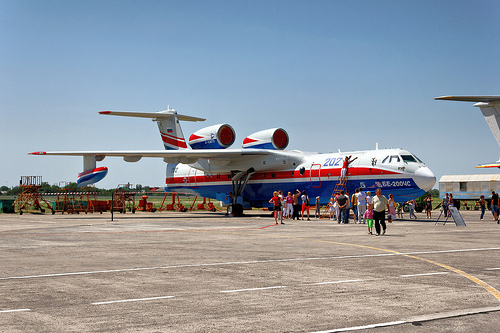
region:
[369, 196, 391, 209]
Person wearing white shirt.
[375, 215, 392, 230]
Person wearing black pants.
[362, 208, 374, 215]
Person wearing pink shirt.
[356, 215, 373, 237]
Person wearing green pants.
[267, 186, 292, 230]
Person wearing red shirt.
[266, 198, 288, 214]
Person wearing black shorts.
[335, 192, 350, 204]
Person wearing gray shirt.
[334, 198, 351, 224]
Person wearing blue jeans.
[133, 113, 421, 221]
Large airplane parked in lot.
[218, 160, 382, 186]
Red stripe along side of plane.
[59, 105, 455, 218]
red white and blue plane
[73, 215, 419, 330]
white lines on tarmac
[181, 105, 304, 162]
two engines on plane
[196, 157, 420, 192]
red stripe on plane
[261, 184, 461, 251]
people in front of plane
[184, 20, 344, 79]
blue and clear sky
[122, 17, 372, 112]
no clouds in sky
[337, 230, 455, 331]
yellow line on tarmac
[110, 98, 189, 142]
white and red tail wing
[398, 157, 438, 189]
white tip of plane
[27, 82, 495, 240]
a pictue of an airfield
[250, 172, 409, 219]
these people are exiting the plane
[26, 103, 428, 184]
this plane is blue and white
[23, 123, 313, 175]
the wing on this plane is long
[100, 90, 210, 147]
this is the plane's tail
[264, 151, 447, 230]
these people are leaving the plane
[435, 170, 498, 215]
a small building in the background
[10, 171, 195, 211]
ground equipment on the airfield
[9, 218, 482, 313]
parts of the land strip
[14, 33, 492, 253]
a bright sunny day over the airfield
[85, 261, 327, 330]
white lines on tarmac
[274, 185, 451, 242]
people are near plane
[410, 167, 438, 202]
white nose on plane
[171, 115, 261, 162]
red white and blue engine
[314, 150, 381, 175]
blue numbers on plane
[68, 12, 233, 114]
sky is blue and clear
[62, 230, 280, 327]
tarmac is light grey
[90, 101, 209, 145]
red and white tail wings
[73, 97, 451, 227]
the plane is red, white, and blue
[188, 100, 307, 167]
the engines are on top of the wing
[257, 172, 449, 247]
people are looking at the plane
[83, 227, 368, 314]
the ground is grey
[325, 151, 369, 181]
a person is standing against the plane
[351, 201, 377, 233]
little girl is wearing green pants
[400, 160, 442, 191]
the nose of the plane is white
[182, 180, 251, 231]
person standing under the wing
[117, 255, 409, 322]
white lines on the ground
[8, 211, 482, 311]
a yellow curved line